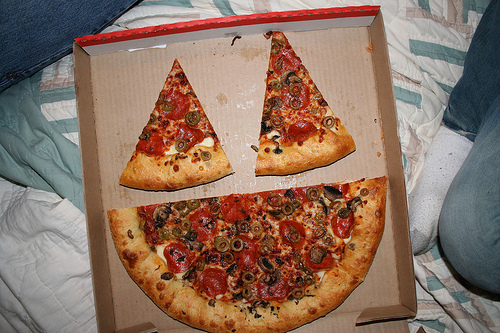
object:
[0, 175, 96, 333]
blanket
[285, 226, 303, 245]
topping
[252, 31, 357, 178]
pizza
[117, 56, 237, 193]
pizza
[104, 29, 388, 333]
face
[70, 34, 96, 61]
corner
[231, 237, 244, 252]
olive slice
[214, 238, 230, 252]
olive slice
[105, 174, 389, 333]
pizza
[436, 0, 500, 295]
jean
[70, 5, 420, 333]
pizza box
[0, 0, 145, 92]
jeans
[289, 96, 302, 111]
olives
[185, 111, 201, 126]
olives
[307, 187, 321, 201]
olives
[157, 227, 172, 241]
toppings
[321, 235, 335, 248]
toppings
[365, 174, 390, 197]
corner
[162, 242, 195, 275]
pepperoni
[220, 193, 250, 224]
pepperoni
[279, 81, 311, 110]
pepperoni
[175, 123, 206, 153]
pepperoni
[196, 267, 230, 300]
pepperoni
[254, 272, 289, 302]
pepperoni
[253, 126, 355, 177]
crust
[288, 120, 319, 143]
pepperoni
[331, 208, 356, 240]
pepperoni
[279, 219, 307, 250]
pepperoni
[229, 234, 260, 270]
pepperoni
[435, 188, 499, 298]
knee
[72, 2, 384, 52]
edge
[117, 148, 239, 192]
crust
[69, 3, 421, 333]
box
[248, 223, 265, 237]
topping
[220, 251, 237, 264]
topping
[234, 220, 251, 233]
topping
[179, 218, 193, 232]
topping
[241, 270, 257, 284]
topping